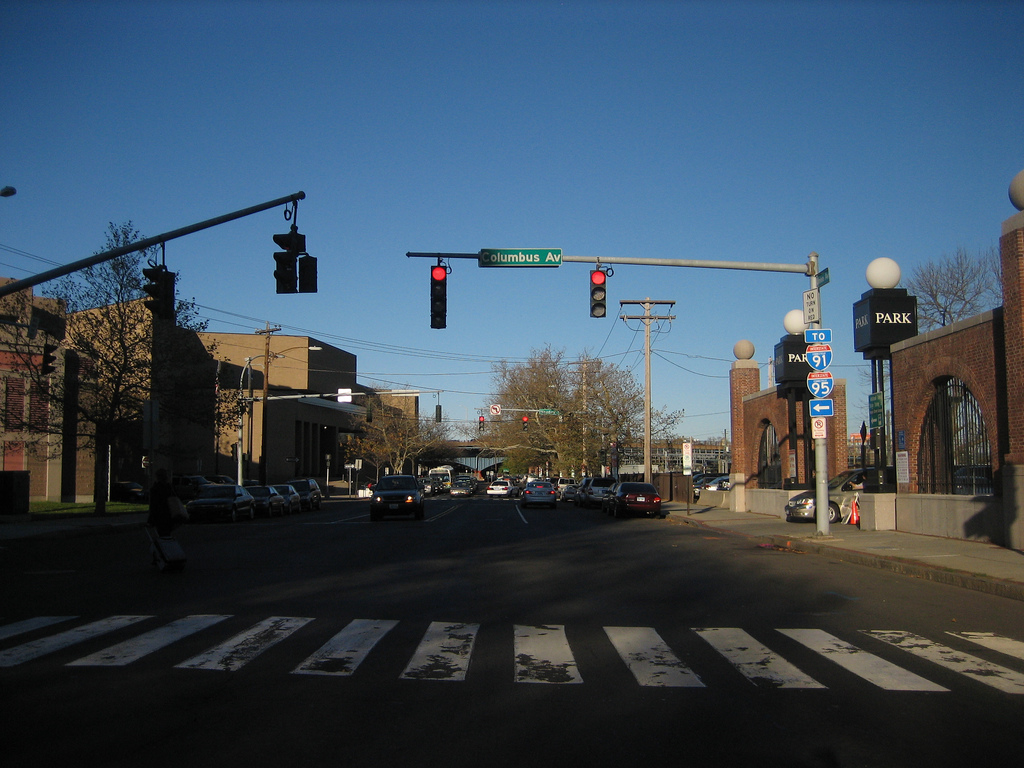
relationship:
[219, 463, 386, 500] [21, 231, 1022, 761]
people enjoy outdoors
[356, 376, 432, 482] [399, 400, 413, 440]
building has wall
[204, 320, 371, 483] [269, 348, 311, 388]
building has wall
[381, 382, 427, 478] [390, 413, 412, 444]
building has wall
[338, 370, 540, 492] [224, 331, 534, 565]
wall with building